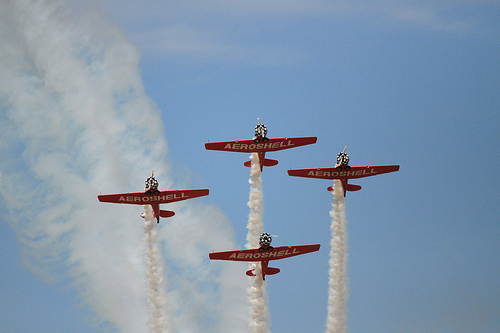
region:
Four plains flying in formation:
[115, 99, 366, 280]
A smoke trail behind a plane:
[320, 171, 354, 311]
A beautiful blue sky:
[240, 29, 460, 91]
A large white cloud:
[17, 27, 184, 205]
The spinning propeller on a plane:
[250, 115, 273, 143]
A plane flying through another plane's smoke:
[204, 225, 321, 285]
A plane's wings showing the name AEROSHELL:
[192, 135, 325, 157]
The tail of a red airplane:
[245, 265, 286, 286]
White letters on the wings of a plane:
[306, 167, 375, 181]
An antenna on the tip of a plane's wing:
[284, 165, 293, 171]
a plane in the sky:
[94, 173, 217, 227]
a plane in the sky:
[206, 218, 326, 303]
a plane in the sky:
[286, 141, 408, 219]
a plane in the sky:
[204, 95, 324, 184]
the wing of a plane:
[207, 245, 255, 272]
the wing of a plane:
[270, 241, 319, 259]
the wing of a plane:
[162, 187, 212, 202]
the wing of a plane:
[97, 190, 140, 210]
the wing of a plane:
[206, 133, 253, 160]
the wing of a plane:
[270, 137, 317, 152]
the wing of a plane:
[288, 162, 330, 190]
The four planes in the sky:
[94, 113, 406, 284]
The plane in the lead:
[199, 119, 320, 180]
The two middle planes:
[93, 146, 401, 223]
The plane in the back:
[205, 221, 325, 283]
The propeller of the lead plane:
[247, 115, 270, 143]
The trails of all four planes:
[137, 279, 353, 331]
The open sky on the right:
[406, 5, 497, 330]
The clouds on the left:
[0, 0, 263, 328]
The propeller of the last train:
[251, 228, 277, 249]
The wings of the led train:
[203, 133, 320, 153]